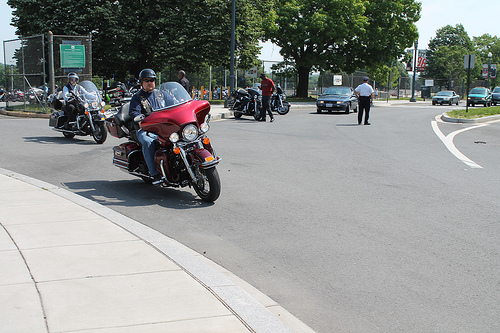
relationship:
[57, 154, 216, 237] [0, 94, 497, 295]
shadow on street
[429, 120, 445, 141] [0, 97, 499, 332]
white line in street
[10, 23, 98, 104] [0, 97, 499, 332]
fencing near street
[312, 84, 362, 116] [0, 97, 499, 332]
black car driving in street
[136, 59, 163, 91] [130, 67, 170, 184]
helmet on man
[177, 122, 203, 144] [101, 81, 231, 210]
light on front of motor cycle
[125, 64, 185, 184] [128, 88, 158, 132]
man wearing shirt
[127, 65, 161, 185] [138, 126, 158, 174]
person wearing blue jeans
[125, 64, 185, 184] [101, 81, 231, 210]
man on motor cycle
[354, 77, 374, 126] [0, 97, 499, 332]
person standing in street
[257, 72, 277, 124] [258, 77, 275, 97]
person wearing shirt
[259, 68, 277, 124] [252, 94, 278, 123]
person wearing pants.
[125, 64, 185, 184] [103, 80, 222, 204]
man on motorcycle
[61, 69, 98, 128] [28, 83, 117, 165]
man on black motorcycle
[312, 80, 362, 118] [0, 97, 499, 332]
black car drives on street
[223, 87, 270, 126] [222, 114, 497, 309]
motorcycle on street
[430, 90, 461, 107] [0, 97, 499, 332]
car in street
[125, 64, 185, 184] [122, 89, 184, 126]
man wears shirt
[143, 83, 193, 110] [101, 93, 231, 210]
window on motor cycle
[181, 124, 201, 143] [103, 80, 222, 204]
headlight on motorcycle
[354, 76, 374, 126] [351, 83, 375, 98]
person wears shirt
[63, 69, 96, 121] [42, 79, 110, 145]
man rides black motorcycle